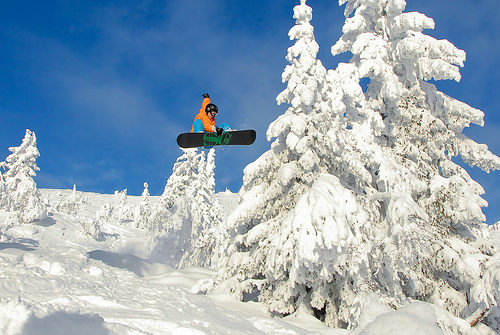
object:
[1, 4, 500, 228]
sky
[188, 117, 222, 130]
ski pant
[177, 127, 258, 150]
snowboard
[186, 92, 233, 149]
person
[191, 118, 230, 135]
pants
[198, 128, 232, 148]
logo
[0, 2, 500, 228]
clouds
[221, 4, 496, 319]
pine tree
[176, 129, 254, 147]
black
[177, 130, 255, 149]
skitting board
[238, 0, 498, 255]
snow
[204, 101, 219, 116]
helmet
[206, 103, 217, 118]
head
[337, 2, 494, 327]
tree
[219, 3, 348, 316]
tree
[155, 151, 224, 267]
tree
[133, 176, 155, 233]
tree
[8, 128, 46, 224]
tree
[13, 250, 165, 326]
snow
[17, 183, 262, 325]
hill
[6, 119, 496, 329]
mountain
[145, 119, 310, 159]
snowboard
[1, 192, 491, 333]
ground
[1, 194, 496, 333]
snow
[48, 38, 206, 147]
sky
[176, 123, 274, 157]
snowboard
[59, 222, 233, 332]
snow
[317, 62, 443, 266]
tree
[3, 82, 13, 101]
cloud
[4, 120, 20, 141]
cloud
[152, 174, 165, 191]
cloud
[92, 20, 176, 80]
cloud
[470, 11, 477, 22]
cloud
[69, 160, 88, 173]
cloud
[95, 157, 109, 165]
cloud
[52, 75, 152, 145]
cloud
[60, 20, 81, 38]
cloud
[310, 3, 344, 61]
cloud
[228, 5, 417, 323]
tree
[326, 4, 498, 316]
tree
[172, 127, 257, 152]
snowboard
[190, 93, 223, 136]
man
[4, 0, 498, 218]
sky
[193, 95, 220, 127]
top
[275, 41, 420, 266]
snow